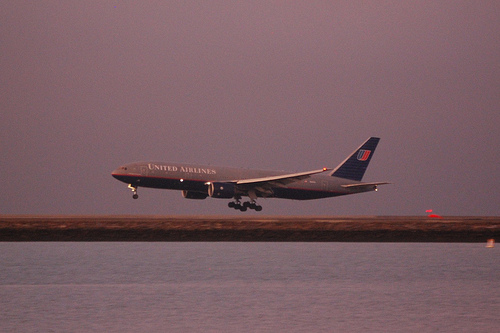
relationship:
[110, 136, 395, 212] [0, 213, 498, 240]
aircraft over land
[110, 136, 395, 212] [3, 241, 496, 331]
aircraft over water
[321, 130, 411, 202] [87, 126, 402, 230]
wings of aircraft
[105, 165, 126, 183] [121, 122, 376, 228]
nose cone of airplane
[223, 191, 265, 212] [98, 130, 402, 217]
gear of airplane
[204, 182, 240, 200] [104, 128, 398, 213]
engine of aircraft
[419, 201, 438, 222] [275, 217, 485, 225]
windsock on airstrip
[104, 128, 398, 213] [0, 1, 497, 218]
aircraft in sky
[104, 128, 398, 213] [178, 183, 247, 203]
aircraft with engines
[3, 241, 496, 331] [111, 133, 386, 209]
water beside plane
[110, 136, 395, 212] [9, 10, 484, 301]
aircraft in air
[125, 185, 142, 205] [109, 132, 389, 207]
wheels of plane's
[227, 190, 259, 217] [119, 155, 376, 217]
round wheels under plane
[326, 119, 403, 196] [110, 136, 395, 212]
tail in rear of aircraft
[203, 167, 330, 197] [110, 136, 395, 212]
wing on a side of aircraft